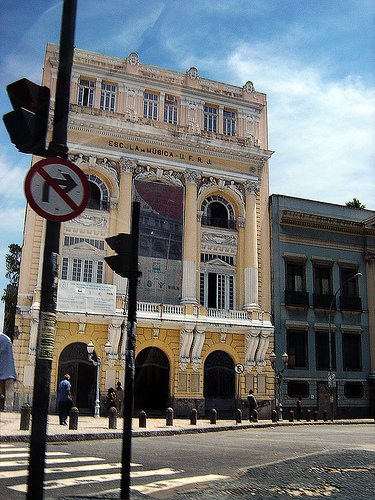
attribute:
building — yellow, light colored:
[2, 40, 276, 409]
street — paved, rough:
[2, 410, 370, 494]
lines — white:
[0, 441, 231, 499]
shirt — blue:
[55, 378, 73, 402]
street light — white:
[84, 338, 113, 419]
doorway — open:
[133, 344, 173, 417]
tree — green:
[1, 241, 21, 347]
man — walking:
[56, 371, 73, 425]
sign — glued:
[34, 312, 58, 364]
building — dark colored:
[270, 195, 374, 412]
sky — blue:
[274, 10, 372, 190]